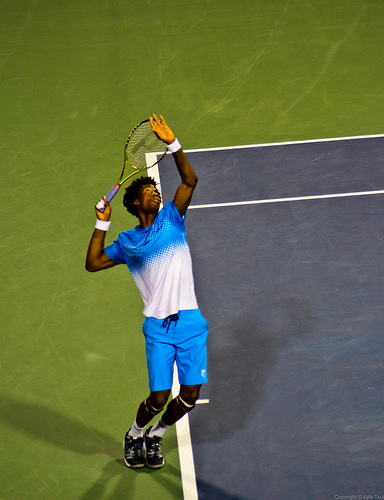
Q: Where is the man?
A: Tennis court.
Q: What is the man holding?
A: A tennis racket.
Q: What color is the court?
A: Blue and green.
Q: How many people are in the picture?
A: 1.